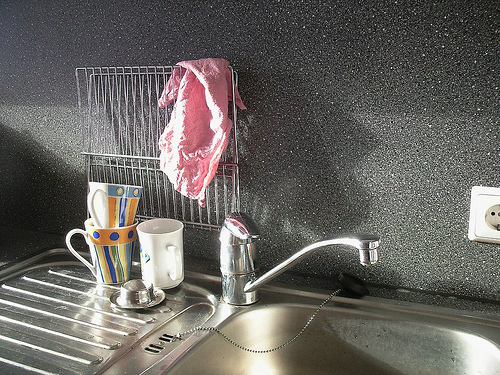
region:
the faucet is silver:
[220, 211, 385, 312]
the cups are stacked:
[57, 181, 139, 291]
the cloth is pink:
[151, 51, 239, 199]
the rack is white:
[85, 72, 142, 157]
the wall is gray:
[309, 87, 427, 180]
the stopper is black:
[327, 276, 380, 300]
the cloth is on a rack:
[71, 59, 253, 181]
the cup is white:
[125, 218, 193, 292]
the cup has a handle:
[63, 219, 93, 292]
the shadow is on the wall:
[255, 88, 362, 210]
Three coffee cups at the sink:
[70, 170, 182, 295]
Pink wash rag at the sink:
[172, 58, 228, 188]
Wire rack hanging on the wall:
[76, 67, 149, 167]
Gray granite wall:
[326, 56, 454, 209]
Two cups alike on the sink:
[82, 180, 136, 281]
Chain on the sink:
[176, 324, 324, 354]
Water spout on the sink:
[217, 211, 386, 305]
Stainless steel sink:
[251, 310, 487, 374]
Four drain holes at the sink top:
[143, 323, 180, 358]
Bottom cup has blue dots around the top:
[79, 222, 134, 247]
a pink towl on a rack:
[136, 53, 251, 190]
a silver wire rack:
[40, 43, 262, 260]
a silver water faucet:
[197, 209, 439, 341]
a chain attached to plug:
[158, 270, 377, 350]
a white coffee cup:
[141, 220, 191, 284]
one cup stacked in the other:
[56, 168, 147, 293]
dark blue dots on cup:
[91, 228, 140, 246]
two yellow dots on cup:
[106, 184, 143, 200]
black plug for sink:
[330, 273, 380, 307]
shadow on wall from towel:
[230, 73, 382, 241]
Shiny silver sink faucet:
[212, 204, 386, 308]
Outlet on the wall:
[451, 174, 498, 249]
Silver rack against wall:
[65, 58, 252, 255]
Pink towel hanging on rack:
[153, 53, 245, 211]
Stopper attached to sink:
[161, 274, 377, 354]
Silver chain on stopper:
[170, 288, 337, 350]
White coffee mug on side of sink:
[136, 216, 193, 296]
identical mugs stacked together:
[53, 171, 139, 291]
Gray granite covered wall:
[0, 2, 498, 309]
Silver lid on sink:
[100, 273, 170, 318]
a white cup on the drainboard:
[135, 216, 185, 289]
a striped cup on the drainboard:
[57, 218, 133, 279]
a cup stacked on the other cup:
[82, 180, 140, 234]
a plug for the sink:
[156, 270, 375, 369]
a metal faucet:
[215, 208, 382, 313]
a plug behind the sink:
[464, 179, 499, 256]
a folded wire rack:
[60, 50, 253, 241]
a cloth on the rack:
[152, 51, 253, 207]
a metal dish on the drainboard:
[107, 277, 167, 314]